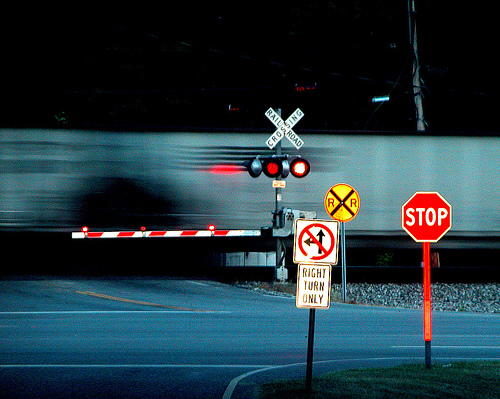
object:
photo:
[0, 0, 499, 397]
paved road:
[0, 276, 499, 396]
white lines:
[0, 360, 280, 366]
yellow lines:
[76, 289, 209, 314]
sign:
[399, 192, 451, 242]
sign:
[323, 180, 360, 222]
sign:
[291, 218, 341, 265]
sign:
[294, 262, 330, 309]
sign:
[263, 106, 303, 149]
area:
[314, 340, 498, 397]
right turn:
[295, 263, 330, 308]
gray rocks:
[438, 287, 498, 316]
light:
[291, 157, 311, 178]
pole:
[421, 242, 432, 373]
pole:
[339, 222, 348, 302]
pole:
[303, 309, 315, 394]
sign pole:
[421, 241, 429, 368]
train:
[0, 127, 500, 268]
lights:
[208, 224, 216, 232]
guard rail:
[69, 229, 268, 241]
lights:
[263, 158, 286, 178]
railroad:
[2, 245, 498, 278]